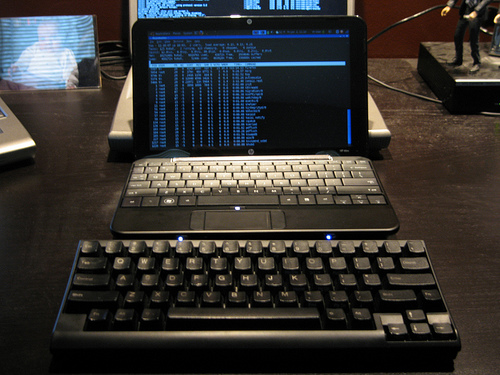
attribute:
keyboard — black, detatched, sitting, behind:
[47, 236, 462, 354]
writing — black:
[148, 30, 271, 150]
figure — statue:
[440, 0, 490, 75]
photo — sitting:
[0, 11, 104, 96]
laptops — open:
[106, 1, 400, 236]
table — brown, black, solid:
[1, 56, 498, 374]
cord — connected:
[367, 1, 499, 118]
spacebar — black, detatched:
[165, 306, 321, 330]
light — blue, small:
[322, 233, 333, 242]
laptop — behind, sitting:
[104, 1, 400, 150]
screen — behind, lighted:
[134, 0, 349, 20]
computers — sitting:
[46, 1, 463, 357]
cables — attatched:
[96, 38, 132, 84]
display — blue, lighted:
[136, 1, 324, 152]